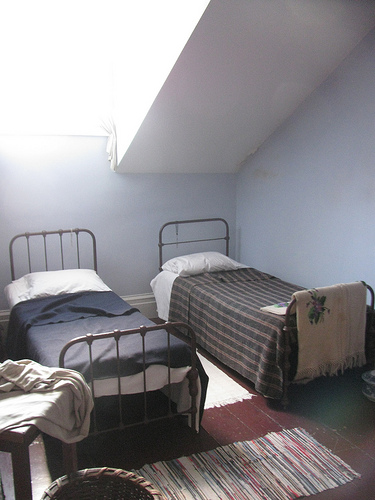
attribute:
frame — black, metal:
[9, 226, 97, 267]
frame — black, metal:
[155, 216, 230, 259]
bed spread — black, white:
[166, 265, 352, 403]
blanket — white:
[286, 278, 372, 388]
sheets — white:
[148, 251, 249, 321]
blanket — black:
[6, 289, 209, 433]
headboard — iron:
[5, 226, 98, 275]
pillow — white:
[12, 263, 107, 298]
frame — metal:
[57, 370, 200, 435]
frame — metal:
[278, 340, 373, 404]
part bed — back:
[213, 278, 245, 292]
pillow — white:
[160, 250, 239, 275]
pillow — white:
[15, 268, 101, 295]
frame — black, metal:
[159, 216, 228, 269]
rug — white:
[155, 306, 272, 430]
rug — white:
[195, 349, 253, 410]